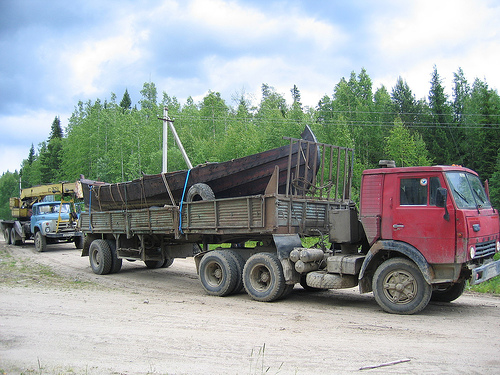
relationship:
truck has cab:
[80, 162, 499, 305] [330, 162, 499, 309]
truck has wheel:
[80, 162, 499, 305] [371, 258, 429, 311]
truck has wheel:
[80, 162, 499, 305] [243, 252, 283, 302]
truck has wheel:
[80, 162, 499, 305] [195, 251, 240, 294]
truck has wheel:
[80, 162, 499, 305] [87, 237, 111, 278]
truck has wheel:
[80, 162, 499, 305] [433, 271, 470, 309]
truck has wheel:
[80, 162, 499, 305] [145, 247, 166, 268]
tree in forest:
[46, 116, 61, 189] [0, 81, 499, 207]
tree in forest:
[22, 146, 36, 189] [0, 81, 499, 207]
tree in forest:
[413, 71, 470, 173] [0, 81, 499, 207]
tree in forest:
[454, 82, 499, 179] [0, 81, 499, 207]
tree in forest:
[344, 69, 381, 183] [0, 81, 499, 207]